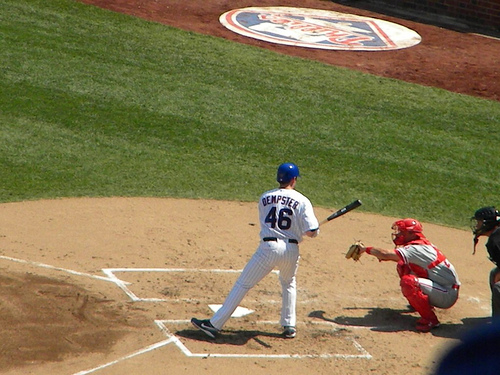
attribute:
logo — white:
[237, 5, 415, 68]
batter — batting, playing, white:
[230, 169, 330, 348]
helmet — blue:
[275, 162, 304, 181]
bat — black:
[335, 196, 368, 226]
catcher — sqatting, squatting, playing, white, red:
[376, 218, 457, 326]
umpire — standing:
[474, 209, 499, 287]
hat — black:
[477, 206, 497, 231]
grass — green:
[102, 34, 200, 121]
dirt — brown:
[425, 41, 458, 72]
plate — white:
[215, 297, 248, 328]